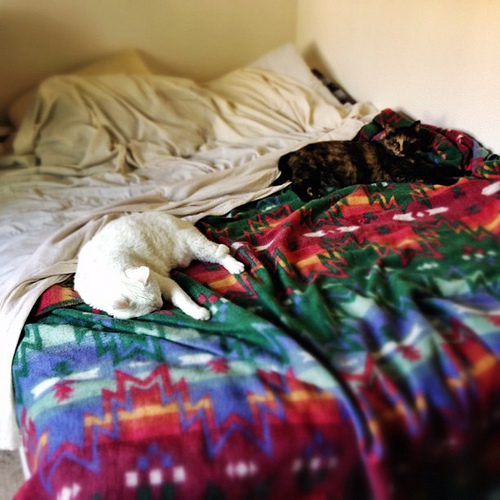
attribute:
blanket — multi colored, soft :
[208, 204, 495, 499]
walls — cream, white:
[4, 1, 496, 95]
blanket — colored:
[9, 324, 195, 479]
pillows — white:
[0, 38, 349, 135]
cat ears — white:
[104, 263, 166, 324]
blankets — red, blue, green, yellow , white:
[46, 191, 477, 493]